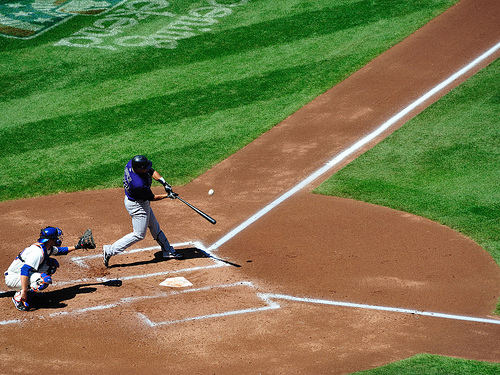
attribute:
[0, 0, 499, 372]
dirt — brown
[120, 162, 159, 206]
jersey — blue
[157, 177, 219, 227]
bat — black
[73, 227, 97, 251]
mitt — black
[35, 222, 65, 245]
helmet — blue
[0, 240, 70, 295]
uniform — white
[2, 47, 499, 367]
lines — white, chalk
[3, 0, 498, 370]
baseball field — dirt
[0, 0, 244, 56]
design — white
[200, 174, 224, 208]
ball — white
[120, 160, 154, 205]
shirt — blue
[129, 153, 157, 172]
helmet — blue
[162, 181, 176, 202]
gloves — black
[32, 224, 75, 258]
helmet — blue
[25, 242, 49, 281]
shirt — white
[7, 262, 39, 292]
pants — white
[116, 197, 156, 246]
pants — grey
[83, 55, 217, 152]
grass — green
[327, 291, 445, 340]
line — white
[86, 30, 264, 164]
grass — green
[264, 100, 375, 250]
line — white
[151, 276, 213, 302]
surface — white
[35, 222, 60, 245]
helmet — blue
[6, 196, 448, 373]
mound — dirt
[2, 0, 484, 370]
field — green, grassy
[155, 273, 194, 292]
diamond — white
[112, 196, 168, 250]
uniform — gray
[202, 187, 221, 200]
ball — white